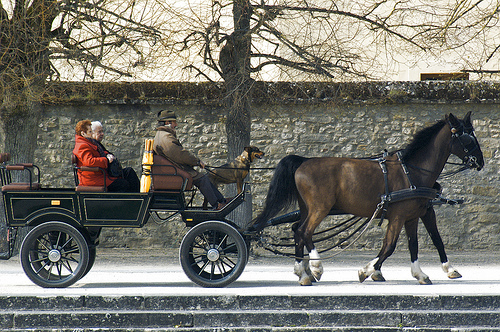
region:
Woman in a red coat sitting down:
[73, 135, 108, 183]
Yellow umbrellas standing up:
[141, 135, 156, 201]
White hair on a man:
[91, 115, 105, 132]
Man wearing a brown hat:
[153, 109, 185, 125]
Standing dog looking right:
[205, 145, 272, 184]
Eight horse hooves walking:
[281, 212, 470, 287]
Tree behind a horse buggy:
[218, 18, 265, 245]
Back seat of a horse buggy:
[2, 143, 47, 192]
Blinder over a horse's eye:
[459, 131, 474, 145]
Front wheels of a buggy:
[170, 215, 258, 289]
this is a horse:
[298, 117, 481, 284]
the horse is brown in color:
[331, 167, 376, 206]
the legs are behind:
[355, 245, 397, 282]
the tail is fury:
[266, 156, 297, 201]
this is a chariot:
[2, 180, 134, 235]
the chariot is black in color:
[96, 192, 139, 221]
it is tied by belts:
[381, 175, 436, 207]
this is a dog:
[226, 135, 263, 180]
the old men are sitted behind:
[68, 115, 122, 177]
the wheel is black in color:
[181, 223, 246, 285]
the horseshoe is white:
[339, 237, 497, 301]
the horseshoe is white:
[287, 238, 439, 322]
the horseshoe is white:
[340, 254, 447, 314]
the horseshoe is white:
[353, 225, 421, 313]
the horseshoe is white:
[357, 272, 402, 312]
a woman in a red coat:
[70, 115, 121, 186]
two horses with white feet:
[265, 103, 495, 285]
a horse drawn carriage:
[7, 106, 489, 290]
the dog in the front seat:
[202, 136, 264, 211]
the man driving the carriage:
[153, 112, 218, 212]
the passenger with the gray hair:
[91, 114, 122, 178]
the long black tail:
[245, 144, 302, 236]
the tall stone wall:
[18, 79, 493, 249]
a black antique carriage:
[1, 161, 249, 288]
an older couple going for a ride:
[69, 116, 138, 195]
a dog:
[200, 130, 260, 215]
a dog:
[213, 114, 302, 225]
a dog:
[228, 127, 274, 214]